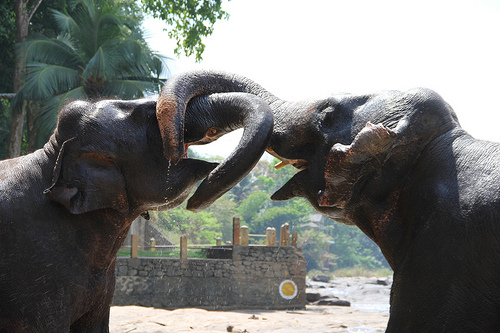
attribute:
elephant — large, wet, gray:
[155, 66, 499, 331]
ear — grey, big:
[37, 136, 134, 223]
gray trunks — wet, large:
[150, 68, 311, 230]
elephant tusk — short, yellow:
[153, 73, 203, 171]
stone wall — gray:
[141, 259, 300, 315]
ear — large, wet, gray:
[43, 102, 145, 224]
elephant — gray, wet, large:
[1, 90, 273, 330]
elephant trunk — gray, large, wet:
[156, 66, 279, 216]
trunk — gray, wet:
[167, 93, 267, 208]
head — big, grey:
[48, 93, 231, 218]